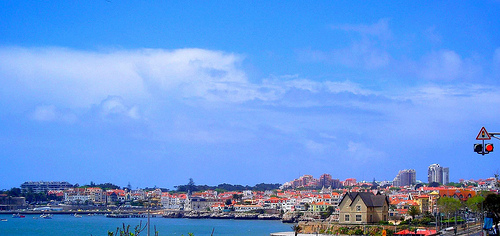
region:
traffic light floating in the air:
[474, 138, 499, 160]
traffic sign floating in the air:
[476, 123, 498, 143]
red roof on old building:
[441, 185, 464, 200]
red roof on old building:
[312, 199, 329, 206]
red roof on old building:
[216, 190, 233, 197]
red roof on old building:
[108, 186, 123, 194]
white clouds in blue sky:
[22, 21, 66, 56]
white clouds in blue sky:
[345, 8, 362, 26]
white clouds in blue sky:
[124, 32, 169, 69]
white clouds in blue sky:
[187, 71, 249, 115]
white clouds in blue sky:
[280, 66, 348, 128]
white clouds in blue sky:
[55, 29, 105, 73]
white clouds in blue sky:
[104, 102, 166, 142]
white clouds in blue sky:
[151, 43, 221, 88]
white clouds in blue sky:
[388, 18, 453, 73]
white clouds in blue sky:
[270, 79, 345, 149]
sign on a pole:
[465, 123, 490, 164]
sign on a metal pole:
[467, 113, 499, 163]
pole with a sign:
[472, 118, 499, 173]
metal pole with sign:
[467, 123, 493, 168]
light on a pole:
[472, 118, 479, 165]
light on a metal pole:
[472, 117, 499, 147]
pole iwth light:
[457, 130, 499, 162]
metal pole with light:
[469, 128, 497, 156]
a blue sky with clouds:
[40, 22, 362, 168]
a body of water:
[21, 211, 103, 234]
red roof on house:
[165, 188, 182, 203]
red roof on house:
[268, 189, 295, 207]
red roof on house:
[311, 191, 325, 215]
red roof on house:
[387, 185, 410, 202]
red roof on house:
[427, 182, 441, 192]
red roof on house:
[405, 185, 430, 200]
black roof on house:
[350, 186, 391, 216]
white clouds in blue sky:
[76, 38, 116, 78]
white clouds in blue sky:
[26, 65, 72, 92]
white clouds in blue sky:
[97, 116, 152, 146]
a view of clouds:
[153, 43, 221, 78]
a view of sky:
[210, 116, 309, 157]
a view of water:
[209, 218, 243, 233]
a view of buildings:
[268, 176, 328, 214]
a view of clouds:
[136, 53, 176, 96]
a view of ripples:
[184, 208, 219, 226]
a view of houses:
[207, 170, 348, 227]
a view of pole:
[457, 107, 493, 164]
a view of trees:
[51, 173, 97, 197]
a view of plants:
[149, 171, 202, 190]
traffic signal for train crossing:
[472, 125, 497, 155]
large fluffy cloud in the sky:
[4, 42, 231, 137]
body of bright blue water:
[3, 208, 301, 234]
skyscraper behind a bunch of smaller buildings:
[429, 161, 448, 187]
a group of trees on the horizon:
[175, 176, 287, 189]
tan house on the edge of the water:
[336, 189, 389, 226]